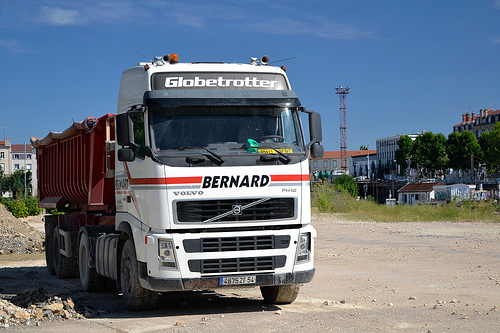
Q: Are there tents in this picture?
A: No, there are no tents.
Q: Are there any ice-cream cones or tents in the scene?
A: No, there are no tents or ice-cream cones.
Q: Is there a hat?
A: Yes, there is a hat.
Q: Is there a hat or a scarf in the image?
A: Yes, there is a hat.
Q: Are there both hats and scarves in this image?
A: No, there is a hat but no scarves.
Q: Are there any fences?
A: No, there are no fences.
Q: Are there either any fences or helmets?
A: No, there are no fences or helmets.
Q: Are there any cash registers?
A: No, there are no cash registers.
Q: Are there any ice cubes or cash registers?
A: No, there are no cash registers or ice cubes.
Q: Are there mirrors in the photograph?
A: Yes, there is a mirror.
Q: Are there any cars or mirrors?
A: Yes, there is a mirror.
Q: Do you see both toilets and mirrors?
A: No, there is a mirror but no toilets.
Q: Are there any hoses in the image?
A: No, there are no hoses.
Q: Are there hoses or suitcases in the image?
A: No, there are no hoses or suitcases.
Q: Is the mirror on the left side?
A: Yes, the mirror is on the left of the image.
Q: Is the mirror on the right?
A: No, the mirror is on the left of the image.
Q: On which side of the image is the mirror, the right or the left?
A: The mirror is on the left of the image.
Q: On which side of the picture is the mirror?
A: The mirror is on the left of the image.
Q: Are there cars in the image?
A: No, there are no cars.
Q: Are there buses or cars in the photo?
A: No, there are no cars or buses.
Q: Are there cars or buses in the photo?
A: No, there are no cars or buses.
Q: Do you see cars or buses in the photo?
A: No, there are no cars or buses.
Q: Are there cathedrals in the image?
A: No, there are no cathedrals.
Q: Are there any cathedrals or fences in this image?
A: No, there are no cathedrals or fences.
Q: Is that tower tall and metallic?
A: Yes, the tower is tall and metallic.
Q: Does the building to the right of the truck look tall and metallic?
A: Yes, the tower is tall and metallic.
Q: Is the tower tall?
A: Yes, the tower is tall.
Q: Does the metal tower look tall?
A: Yes, the tower is tall.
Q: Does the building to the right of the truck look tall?
A: Yes, the tower is tall.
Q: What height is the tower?
A: The tower is tall.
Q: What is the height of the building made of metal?
A: The tower is tall.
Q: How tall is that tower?
A: The tower is tall.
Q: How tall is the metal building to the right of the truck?
A: The tower is tall.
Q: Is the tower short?
A: No, the tower is tall.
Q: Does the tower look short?
A: No, the tower is tall.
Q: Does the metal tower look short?
A: No, the tower is tall.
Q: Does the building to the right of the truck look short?
A: No, the tower is tall.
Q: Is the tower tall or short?
A: The tower is tall.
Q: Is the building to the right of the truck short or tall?
A: The tower is tall.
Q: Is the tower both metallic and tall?
A: Yes, the tower is metallic and tall.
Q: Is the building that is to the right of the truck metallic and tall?
A: Yes, the tower is metallic and tall.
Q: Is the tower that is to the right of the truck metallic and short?
A: No, the tower is metallic but tall.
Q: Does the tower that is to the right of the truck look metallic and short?
A: No, the tower is metallic but tall.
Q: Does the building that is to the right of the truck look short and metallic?
A: No, the tower is metallic but tall.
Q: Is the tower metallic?
A: Yes, the tower is metallic.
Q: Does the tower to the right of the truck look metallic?
A: Yes, the tower is metallic.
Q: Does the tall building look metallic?
A: Yes, the tower is metallic.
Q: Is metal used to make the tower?
A: Yes, the tower is made of metal.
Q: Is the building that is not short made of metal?
A: Yes, the tower is made of metal.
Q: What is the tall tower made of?
A: The tower is made of metal.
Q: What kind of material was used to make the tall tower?
A: The tower is made of metal.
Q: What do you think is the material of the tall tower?
A: The tower is made of metal.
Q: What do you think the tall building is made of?
A: The tower is made of metal.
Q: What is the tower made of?
A: The tower is made of metal.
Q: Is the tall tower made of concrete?
A: No, the tower is made of metal.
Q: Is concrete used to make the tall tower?
A: No, the tower is made of metal.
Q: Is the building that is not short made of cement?
A: No, the tower is made of metal.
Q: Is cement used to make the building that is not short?
A: No, the tower is made of metal.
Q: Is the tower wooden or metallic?
A: The tower is metallic.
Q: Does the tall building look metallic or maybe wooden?
A: The tower is metallic.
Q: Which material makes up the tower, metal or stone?
A: The tower is made of metal.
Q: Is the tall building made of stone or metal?
A: The tower is made of metal.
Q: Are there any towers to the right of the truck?
A: Yes, there is a tower to the right of the truck.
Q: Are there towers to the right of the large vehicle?
A: Yes, there is a tower to the right of the truck.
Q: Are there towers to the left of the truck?
A: No, the tower is to the right of the truck.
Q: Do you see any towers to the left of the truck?
A: No, the tower is to the right of the truck.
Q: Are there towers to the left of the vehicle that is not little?
A: No, the tower is to the right of the truck.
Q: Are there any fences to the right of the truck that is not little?
A: No, there is a tower to the right of the truck.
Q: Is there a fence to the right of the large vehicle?
A: No, there is a tower to the right of the truck.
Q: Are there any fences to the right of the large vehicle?
A: No, there is a tower to the right of the truck.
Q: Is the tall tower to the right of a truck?
A: Yes, the tower is to the right of a truck.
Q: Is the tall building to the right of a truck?
A: Yes, the tower is to the right of a truck.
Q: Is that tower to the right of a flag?
A: No, the tower is to the right of a truck.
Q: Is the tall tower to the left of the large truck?
A: No, the tower is to the right of the truck.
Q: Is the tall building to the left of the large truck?
A: No, the tower is to the right of the truck.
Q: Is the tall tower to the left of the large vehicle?
A: No, the tower is to the right of the truck.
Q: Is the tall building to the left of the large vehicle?
A: No, the tower is to the right of the truck.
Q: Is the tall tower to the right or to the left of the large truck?
A: The tower is to the right of the truck.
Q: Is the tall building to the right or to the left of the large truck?
A: The tower is to the right of the truck.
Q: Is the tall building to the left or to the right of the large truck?
A: The tower is to the right of the truck.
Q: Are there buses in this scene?
A: No, there are no buses.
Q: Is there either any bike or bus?
A: No, there are no buses or bikes.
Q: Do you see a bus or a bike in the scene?
A: No, there are no buses or bikes.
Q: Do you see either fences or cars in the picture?
A: No, there are no cars or fences.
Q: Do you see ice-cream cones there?
A: No, there are no ice-cream cones.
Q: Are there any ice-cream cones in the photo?
A: No, there are no ice-cream cones.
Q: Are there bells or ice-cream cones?
A: No, there are no ice-cream cones or bells.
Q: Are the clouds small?
A: Yes, the clouds are small.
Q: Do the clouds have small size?
A: Yes, the clouds are small.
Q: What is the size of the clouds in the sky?
A: The clouds are small.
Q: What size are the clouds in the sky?
A: The clouds are small.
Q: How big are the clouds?
A: The clouds are small.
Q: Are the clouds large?
A: No, the clouds are small.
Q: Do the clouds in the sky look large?
A: No, the clouds are small.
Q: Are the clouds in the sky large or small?
A: The clouds are small.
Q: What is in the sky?
A: The clouds are in the sky.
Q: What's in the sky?
A: The clouds are in the sky.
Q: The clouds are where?
A: The clouds are in the sky.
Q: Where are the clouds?
A: The clouds are in the sky.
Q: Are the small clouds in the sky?
A: Yes, the clouds are in the sky.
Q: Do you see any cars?
A: No, there are no cars.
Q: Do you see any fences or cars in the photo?
A: No, there are no cars or fences.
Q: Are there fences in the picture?
A: No, there are no fences.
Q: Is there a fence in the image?
A: No, there are no fences.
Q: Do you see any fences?
A: No, there are no fences.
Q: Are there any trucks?
A: Yes, there is a truck.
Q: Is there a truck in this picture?
A: Yes, there is a truck.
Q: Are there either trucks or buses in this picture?
A: Yes, there is a truck.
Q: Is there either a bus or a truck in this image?
A: Yes, there is a truck.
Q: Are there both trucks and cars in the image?
A: No, there is a truck but no cars.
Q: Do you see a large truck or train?
A: Yes, there is a large truck.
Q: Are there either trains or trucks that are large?
A: Yes, the truck is large.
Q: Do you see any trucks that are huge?
A: Yes, there is a huge truck.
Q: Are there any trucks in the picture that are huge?
A: Yes, there is a truck that is huge.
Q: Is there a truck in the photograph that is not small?
A: Yes, there is a huge truck.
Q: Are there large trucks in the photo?
A: Yes, there is a large truck.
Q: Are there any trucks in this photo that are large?
A: Yes, there is a truck that is large.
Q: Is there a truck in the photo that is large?
A: Yes, there is a truck that is large.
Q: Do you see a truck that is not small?
A: Yes, there is a large truck.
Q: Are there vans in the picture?
A: No, there are no vans.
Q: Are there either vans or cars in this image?
A: No, there are no vans or cars.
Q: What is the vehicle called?
A: The vehicle is a truck.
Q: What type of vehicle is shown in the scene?
A: The vehicle is a truck.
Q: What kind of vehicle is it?
A: The vehicle is a truck.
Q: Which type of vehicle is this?
A: This is a truck.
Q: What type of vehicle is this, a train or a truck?
A: This is a truck.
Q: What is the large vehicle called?
A: The vehicle is a truck.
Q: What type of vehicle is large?
A: The vehicle is a truck.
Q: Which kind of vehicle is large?
A: The vehicle is a truck.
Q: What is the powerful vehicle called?
A: The vehicle is a truck.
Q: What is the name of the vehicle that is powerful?
A: The vehicle is a truck.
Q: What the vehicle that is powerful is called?
A: The vehicle is a truck.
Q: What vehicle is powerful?
A: The vehicle is a truck.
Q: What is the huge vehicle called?
A: The vehicle is a truck.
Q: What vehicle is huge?
A: The vehicle is a truck.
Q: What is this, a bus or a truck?
A: This is a truck.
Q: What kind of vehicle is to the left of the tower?
A: The vehicle is a truck.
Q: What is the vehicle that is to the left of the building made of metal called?
A: The vehicle is a truck.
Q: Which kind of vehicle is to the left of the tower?
A: The vehicle is a truck.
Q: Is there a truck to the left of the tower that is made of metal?
A: Yes, there is a truck to the left of the tower.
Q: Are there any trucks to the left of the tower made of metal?
A: Yes, there is a truck to the left of the tower.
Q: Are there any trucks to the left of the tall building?
A: Yes, there is a truck to the left of the tower.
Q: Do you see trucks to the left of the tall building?
A: Yes, there is a truck to the left of the tower.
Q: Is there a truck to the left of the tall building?
A: Yes, there is a truck to the left of the tower.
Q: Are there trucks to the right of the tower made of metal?
A: No, the truck is to the left of the tower.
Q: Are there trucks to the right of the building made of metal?
A: No, the truck is to the left of the tower.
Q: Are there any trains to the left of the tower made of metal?
A: No, there is a truck to the left of the tower.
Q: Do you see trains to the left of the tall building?
A: No, there is a truck to the left of the tower.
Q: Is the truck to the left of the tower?
A: Yes, the truck is to the left of the tower.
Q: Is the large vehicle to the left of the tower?
A: Yes, the truck is to the left of the tower.